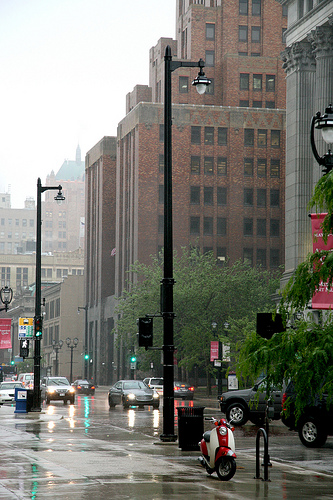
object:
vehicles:
[280, 349, 332, 448]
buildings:
[82, 135, 116, 385]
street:
[0, 365, 333, 500]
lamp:
[28, 176, 66, 414]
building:
[84, 0, 290, 385]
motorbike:
[198, 413, 238, 481]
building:
[279, 0, 333, 335]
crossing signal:
[20, 339, 29, 357]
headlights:
[48, 387, 74, 394]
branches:
[218, 307, 333, 432]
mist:
[0, 146, 87, 269]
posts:
[160, 44, 175, 441]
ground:
[1, 378, 333, 499]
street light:
[159, 44, 211, 445]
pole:
[169, 58, 206, 71]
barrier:
[253, 428, 272, 481]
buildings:
[0, 268, 88, 384]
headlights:
[127, 393, 159, 401]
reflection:
[30, 462, 38, 498]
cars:
[40, 375, 75, 405]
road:
[0, 389, 333, 500]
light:
[83, 395, 90, 433]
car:
[108, 379, 160, 410]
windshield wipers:
[47, 379, 69, 386]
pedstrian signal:
[22, 339, 28, 348]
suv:
[216, 373, 291, 429]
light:
[35, 318, 42, 336]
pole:
[34, 177, 42, 411]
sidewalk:
[1, 404, 333, 499]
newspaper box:
[14, 387, 28, 413]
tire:
[123, 397, 130, 408]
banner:
[19, 318, 33, 337]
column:
[285, 61, 314, 275]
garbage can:
[175, 406, 206, 451]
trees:
[110, 163, 333, 426]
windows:
[185, 125, 283, 271]